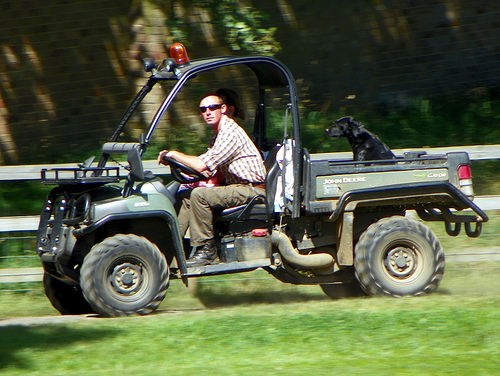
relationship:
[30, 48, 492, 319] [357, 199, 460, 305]
vehicle has tire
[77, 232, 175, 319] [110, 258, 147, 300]
front tire has rim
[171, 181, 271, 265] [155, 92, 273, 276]
pants on human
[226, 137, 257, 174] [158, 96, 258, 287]
shirt on human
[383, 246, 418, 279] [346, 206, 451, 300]
rim of a wheel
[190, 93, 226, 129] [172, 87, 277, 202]
head of a man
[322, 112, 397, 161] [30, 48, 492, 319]
dog in back of vehicle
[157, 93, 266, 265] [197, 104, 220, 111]
man with sunglasses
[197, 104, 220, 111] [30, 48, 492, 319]
sunglasses in vehicle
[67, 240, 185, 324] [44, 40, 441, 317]
front tire of vehicle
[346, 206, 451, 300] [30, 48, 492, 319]
wheel of vehicle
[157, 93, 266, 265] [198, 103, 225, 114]
man wearing sunglasses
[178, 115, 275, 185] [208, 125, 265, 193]
man wearing a shirt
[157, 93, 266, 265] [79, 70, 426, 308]
man driving vehicle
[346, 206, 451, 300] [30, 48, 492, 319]
wheel belongs to vehicle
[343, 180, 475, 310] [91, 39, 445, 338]
wheel belongs to vehicle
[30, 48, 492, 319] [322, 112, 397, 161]
vehicle contains dog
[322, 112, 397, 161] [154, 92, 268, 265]
dog and human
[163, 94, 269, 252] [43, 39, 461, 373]
human rides inside vehicle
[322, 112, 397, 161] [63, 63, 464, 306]
dog rides in back of vehicle